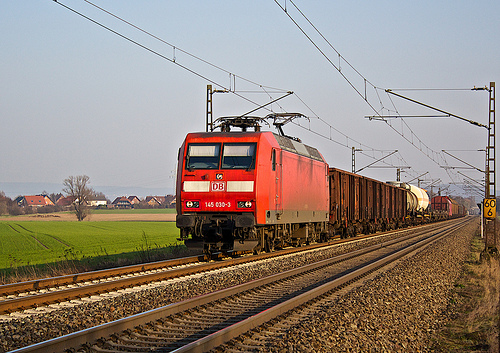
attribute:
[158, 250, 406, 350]
railroads — metal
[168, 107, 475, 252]
freight train — red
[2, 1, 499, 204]
sky — blue 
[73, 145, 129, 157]
clouds — white 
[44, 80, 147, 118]
sky — blue 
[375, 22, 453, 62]
sky — blue 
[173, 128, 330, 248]
engine — Red 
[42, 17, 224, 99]
clouds — white 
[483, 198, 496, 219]
sign — yellow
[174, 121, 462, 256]
train — red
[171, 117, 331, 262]
engine — red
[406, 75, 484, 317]
station — train